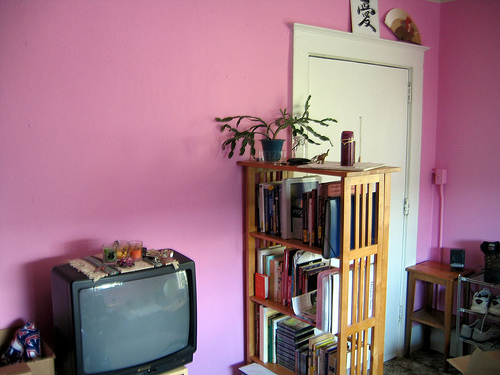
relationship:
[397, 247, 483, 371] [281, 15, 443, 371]
night stand next to door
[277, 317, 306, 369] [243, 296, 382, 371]
dvds on bottom shelf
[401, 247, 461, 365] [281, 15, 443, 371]
table near door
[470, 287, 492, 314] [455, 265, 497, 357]
shoe on rack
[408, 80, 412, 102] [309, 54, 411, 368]
hinge on door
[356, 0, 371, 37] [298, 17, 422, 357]
chinese character on door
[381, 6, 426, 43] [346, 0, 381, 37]
fan by chinese character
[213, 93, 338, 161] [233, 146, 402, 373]
plant on shelf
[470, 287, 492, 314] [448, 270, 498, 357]
shoe on shoe rack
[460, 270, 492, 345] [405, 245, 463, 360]
shoe rack by stand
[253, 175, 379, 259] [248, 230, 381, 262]
books on shelf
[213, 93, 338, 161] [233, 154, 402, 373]
plant on top of bookcase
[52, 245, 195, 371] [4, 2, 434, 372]
black tv by wall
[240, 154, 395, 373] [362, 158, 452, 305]
bookcase near door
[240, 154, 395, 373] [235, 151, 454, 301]
bookcase in room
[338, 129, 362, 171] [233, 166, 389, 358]
bottle on top of shelf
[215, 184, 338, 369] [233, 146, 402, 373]
books on shelf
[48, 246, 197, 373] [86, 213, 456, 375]
television in room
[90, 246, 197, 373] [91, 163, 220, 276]
television set against a pink wall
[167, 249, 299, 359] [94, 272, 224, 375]
box filled with stuff next to a television set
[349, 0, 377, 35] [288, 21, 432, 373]
sign over a door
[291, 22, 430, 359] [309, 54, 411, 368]
door frame on door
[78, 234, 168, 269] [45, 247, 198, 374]
candles on tv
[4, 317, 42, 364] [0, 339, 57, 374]
stuff in box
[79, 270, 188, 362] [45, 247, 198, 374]
reflection on tv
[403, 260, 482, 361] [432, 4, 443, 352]
end table in corner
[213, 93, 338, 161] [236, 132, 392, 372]
plant on book case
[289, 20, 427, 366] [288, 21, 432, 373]
frame on door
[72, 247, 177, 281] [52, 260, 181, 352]
cloth on tv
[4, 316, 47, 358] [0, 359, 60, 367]
piece in box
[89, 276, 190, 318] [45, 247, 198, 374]
glare on tv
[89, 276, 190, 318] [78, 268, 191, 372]
glare on screen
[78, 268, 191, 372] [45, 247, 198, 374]
screen on tv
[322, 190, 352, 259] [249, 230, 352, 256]
blue folder on shelf